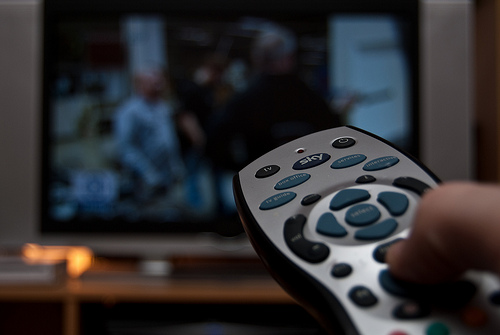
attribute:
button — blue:
[345, 202, 381, 227]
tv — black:
[38, 3, 419, 237]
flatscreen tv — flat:
[33, 1, 427, 281]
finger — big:
[383, 173, 498, 285]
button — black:
[293, 148, 329, 170]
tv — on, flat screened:
[0, 4, 474, 278]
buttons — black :
[235, 159, 329, 244]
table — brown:
[2, 257, 322, 334]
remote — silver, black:
[229, 117, 494, 333]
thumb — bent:
[358, 172, 499, 294]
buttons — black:
[276, 219, 334, 276]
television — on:
[29, 2, 430, 260]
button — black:
[281, 211, 331, 265]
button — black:
[392, 175, 431, 196]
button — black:
[355, 172, 377, 182]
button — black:
[300, 192, 321, 204]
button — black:
[330, 260, 352, 282]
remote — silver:
[226, 120, 493, 311]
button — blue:
[257, 197, 291, 217]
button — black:
[313, 180, 409, 247]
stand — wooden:
[53, 277, 311, 318]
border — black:
[232, 184, 270, 274]